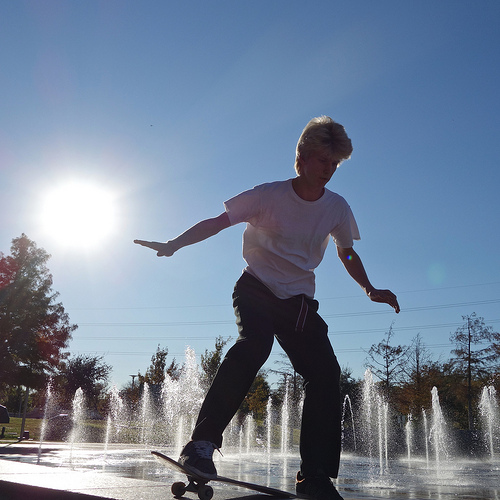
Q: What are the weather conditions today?
A: It is clear.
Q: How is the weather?
A: It is clear.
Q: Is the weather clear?
A: Yes, it is clear.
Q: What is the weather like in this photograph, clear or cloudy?
A: It is clear.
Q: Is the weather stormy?
A: No, it is clear.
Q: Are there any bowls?
A: No, there are no bowls.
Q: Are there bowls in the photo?
A: No, there are no bowls.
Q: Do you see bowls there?
A: No, there are no bowls.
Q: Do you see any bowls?
A: No, there are no bowls.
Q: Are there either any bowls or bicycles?
A: No, there are no bowls or bicycles.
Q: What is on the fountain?
A: The water is on the fountain.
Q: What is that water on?
A: The water is on the fountain.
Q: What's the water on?
A: The water is on the fountain.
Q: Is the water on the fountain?
A: Yes, the water is on the fountain.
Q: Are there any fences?
A: No, there are no fences.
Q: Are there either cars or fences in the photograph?
A: No, there are no fences or cars.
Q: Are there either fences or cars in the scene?
A: No, there are no fences or cars.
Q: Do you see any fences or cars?
A: No, there are no fences or cars.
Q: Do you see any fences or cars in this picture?
A: No, there are no fences or cars.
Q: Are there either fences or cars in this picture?
A: No, there are no fences or cars.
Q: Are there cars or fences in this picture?
A: No, there are no fences or cars.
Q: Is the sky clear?
A: Yes, the sky is clear.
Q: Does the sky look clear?
A: Yes, the sky is clear.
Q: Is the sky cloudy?
A: No, the sky is clear.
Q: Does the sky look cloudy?
A: No, the sky is clear.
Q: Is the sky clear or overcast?
A: The sky is clear.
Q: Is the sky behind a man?
A: Yes, the sky is behind a man.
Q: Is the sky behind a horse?
A: No, the sky is behind a man.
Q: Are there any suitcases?
A: No, there are no suitcases.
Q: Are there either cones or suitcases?
A: No, there are no suitcases or cones.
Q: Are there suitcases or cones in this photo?
A: No, there are no suitcases or cones.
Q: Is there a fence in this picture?
A: No, there are no fences.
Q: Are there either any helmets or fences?
A: No, there are no fences or helmets.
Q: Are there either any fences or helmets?
A: No, there are no fences or helmets.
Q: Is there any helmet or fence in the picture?
A: No, there are no fences or helmets.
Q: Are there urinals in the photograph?
A: No, there are no urinals.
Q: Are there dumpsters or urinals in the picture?
A: No, there are no urinals or dumpsters.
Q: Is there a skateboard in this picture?
A: Yes, there is a skateboard.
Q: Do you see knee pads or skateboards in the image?
A: Yes, there is a skateboard.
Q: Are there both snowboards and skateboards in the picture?
A: No, there is a skateboard but no snowboards.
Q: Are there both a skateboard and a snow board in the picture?
A: No, there is a skateboard but no snowboards.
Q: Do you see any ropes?
A: No, there are no ropes.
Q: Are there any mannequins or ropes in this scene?
A: No, there are no ropes or mannequins.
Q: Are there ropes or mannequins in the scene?
A: No, there are no ropes or mannequins.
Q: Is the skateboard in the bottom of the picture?
A: Yes, the skateboard is in the bottom of the image.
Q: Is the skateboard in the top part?
A: No, the skateboard is in the bottom of the image.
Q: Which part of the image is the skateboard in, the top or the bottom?
A: The skateboard is in the bottom of the image.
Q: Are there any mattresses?
A: No, there are no mattresses.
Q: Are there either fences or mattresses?
A: No, there are no mattresses or fences.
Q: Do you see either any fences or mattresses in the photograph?
A: No, there are no mattresses or fences.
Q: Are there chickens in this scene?
A: No, there are no chickens.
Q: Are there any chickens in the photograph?
A: No, there are no chickens.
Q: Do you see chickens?
A: No, there are no chickens.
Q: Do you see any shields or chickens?
A: No, there are no chickens or shields.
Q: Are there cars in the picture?
A: No, there are no cars.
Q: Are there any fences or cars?
A: No, there are no cars or fences.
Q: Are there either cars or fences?
A: No, there are no cars or fences.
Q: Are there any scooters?
A: No, there are no scooters.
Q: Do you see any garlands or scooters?
A: No, there are no scooters or garlands.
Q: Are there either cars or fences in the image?
A: No, there are no fences or cars.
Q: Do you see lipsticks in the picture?
A: No, there are no lipsticks.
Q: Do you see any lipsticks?
A: No, there are no lipsticks.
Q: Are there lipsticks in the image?
A: No, there are no lipsticks.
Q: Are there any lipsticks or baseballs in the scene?
A: No, there are no lipsticks or baseballs.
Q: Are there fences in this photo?
A: No, there are no fences.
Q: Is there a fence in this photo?
A: No, there are no fences.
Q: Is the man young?
A: Yes, the man is young.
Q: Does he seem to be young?
A: Yes, the man is young.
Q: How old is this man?
A: The man is young.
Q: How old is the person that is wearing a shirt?
A: The man is young.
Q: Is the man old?
A: No, the man is young.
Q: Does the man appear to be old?
A: No, the man is young.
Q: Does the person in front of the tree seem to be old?
A: No, the man is young.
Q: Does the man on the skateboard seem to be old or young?
A: The man is young.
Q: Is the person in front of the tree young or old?
A: The man is young.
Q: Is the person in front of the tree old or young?
A: The man is young.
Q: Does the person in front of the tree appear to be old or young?
A: The man is young.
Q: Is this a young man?
A: Yes, this is a young man.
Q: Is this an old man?
A: No, this is a young man.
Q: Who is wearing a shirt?
A: The man is wearing a shirt.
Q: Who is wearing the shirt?
A: The man is wearing a shirt.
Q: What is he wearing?
A: The man is wearing a shirt.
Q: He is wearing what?
A: The man is wearing a shirt.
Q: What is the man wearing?
A: The man is wearing a shirt.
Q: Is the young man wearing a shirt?
A: Yes, the man is wearing a shirt.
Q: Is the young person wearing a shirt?
A: Yes, the man is wearing a shirt.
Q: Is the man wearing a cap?
A: No, the man is wearing a shirt.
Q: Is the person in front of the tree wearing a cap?
A: No, the man is wearing a shirt.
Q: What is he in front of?
A: The man is in front of the tree.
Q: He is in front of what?
A: The man is in front of the tree.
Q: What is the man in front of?
A: The man is in front of the tree.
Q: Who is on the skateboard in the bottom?
A: The man is on the skateboard.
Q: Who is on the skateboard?
A: The man is on the skateboard.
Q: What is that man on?
A: The man is on the skateboard.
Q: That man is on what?
A: The man is on the skateboard.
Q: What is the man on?
A: The man is on the skateboard.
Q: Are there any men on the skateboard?
A: Yes, there is a man on the skateboard.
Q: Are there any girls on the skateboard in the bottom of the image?
A: No, there is a man on the skateboard.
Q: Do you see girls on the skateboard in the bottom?
A: No, there is a man on the skateboard.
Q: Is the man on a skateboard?
A: Yes, the man is on a skateboard.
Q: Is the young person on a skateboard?
A: Yes, the man is on a skateboard.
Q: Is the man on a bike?
A: No, the man is on a skateboard.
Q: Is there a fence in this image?
A: No, there are no fences.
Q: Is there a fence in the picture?
A: No, there are no fences.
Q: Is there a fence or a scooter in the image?
A: No, there are no fences or scooters.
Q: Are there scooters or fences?
A: No, there are no fences or scooters.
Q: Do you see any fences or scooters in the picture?
A: No, there are no fences or scooters.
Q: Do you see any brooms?
A: No, there are no brooms.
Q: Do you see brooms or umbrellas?
A: No, there are no brooms or umbrellas.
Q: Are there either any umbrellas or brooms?
A: No, there are no brooms or umbrellas.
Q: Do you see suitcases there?
A: No, there are no suitcases.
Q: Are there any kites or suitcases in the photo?
A: No, there are no suitcases or kites.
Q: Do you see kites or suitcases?
A: No, there are no suitcases or kites.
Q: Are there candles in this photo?
A: No, there are no candles.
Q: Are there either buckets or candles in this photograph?
A: No, there are no candles or buckets.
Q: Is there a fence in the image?
A: No, there are no fences.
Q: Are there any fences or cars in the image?
A: No, there are no fences or cars.